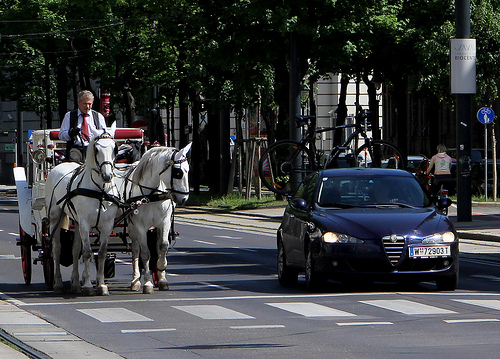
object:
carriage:
[11, 87, 195, 296]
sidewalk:
[0, 285, 500, 358]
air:
[226, 148, 264, 225]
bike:
[421, 172, 459, 215]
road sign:
[476, 107, 497, 125]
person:
[420, 145, 459, 199]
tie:
[82, 111, 91, 140]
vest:
[62, 108, 105, 160]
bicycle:
[257, 101, 408, 197]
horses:
[42, 118, 122, 297]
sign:
[475, 107, 497, 127]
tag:
[413, 246, 451, 260]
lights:
[321, 232, 337, 245]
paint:
[357, 296, 461, 316]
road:
[0, 192, 500, 357]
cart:
[13, 125, 194, 299]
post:
[474, 105, 498, 202]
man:
[59, 90, 110, 167]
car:
[274, 167, 461, 293]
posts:
[446, 0, 476, 228]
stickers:
[449, 34, 478, 100]